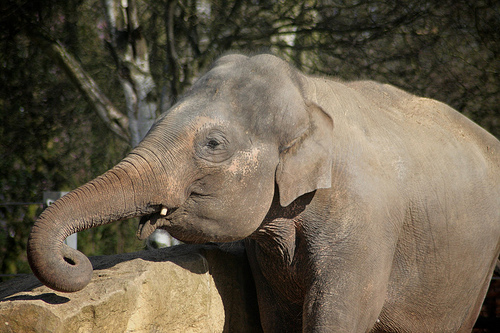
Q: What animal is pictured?
A: Elephant.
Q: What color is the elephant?
A: Gray.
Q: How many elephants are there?
A: One.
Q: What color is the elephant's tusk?
A: White.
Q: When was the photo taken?
A: Daytime.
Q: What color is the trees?
A: Green.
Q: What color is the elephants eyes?
A: Black.